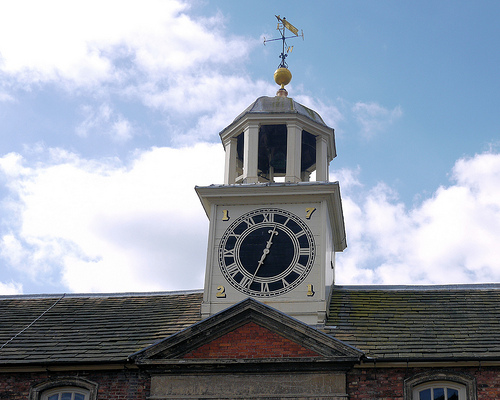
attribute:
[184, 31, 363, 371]
tower — white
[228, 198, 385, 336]
clock — black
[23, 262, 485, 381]
roof — old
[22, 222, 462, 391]
bank — old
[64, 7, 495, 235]
sky — blue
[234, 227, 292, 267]
hands — white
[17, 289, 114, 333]
section — dark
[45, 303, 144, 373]
section — dark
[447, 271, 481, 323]
section — dark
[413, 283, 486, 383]
section — dark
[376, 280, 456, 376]
section — dark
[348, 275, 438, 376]
section — dark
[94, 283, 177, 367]
section — dark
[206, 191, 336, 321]
clock — black, white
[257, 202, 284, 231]
numeral — Roman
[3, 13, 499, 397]
building — brown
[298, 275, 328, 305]
number — golden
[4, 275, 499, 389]
roof — long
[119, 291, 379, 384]
gable — decorative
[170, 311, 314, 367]
brick — red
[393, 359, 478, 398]
window — arched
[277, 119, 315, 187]
column — white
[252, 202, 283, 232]
numeral — white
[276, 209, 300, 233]
numeral — white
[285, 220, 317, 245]
numeral — white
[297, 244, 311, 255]
roman numeral — white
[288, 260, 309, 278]
roman numeral — white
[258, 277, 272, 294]
roman numeral — white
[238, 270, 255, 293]
roman numeral — white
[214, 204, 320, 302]
clock — black, round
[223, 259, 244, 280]
roman numeral — white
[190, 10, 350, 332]
clock tower — white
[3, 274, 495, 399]
building — brick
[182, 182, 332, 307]
clock — blue ad white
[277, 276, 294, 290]
roman —  white